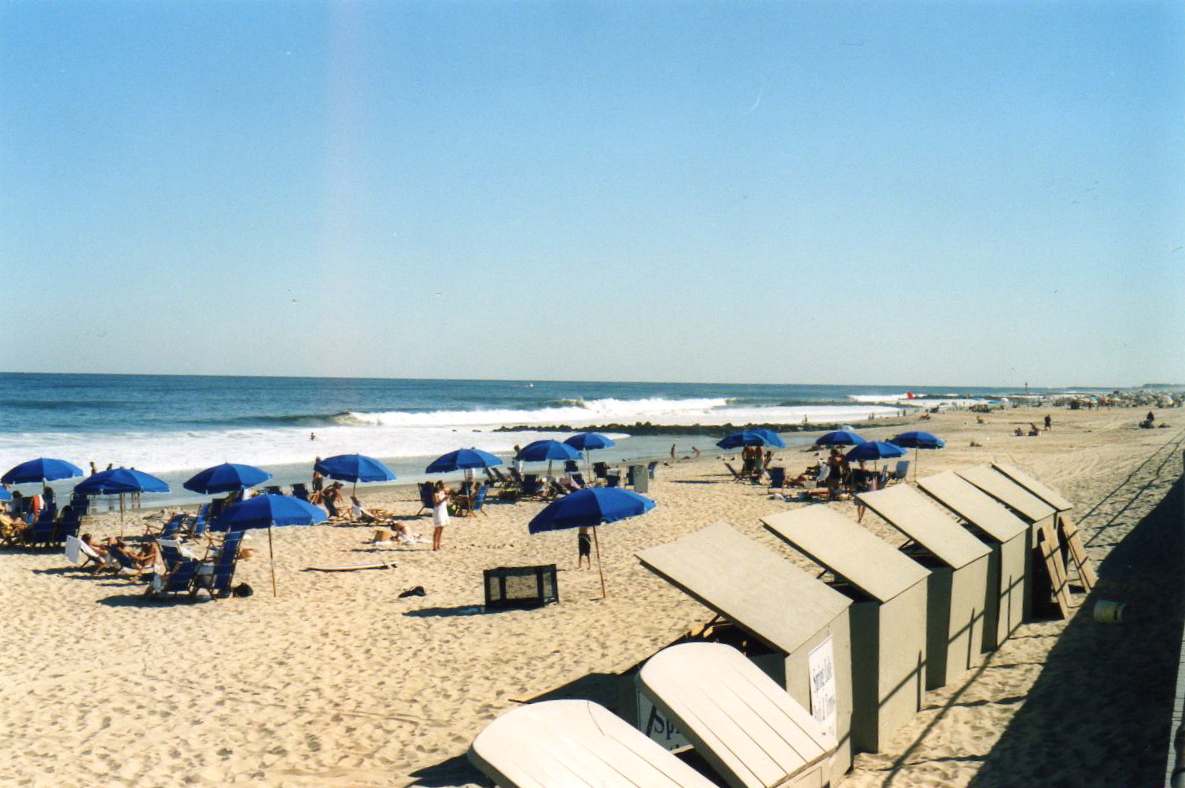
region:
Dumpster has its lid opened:
[631, 518, 862, 785]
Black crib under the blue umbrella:
[482, 560, 559, 609]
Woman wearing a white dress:
[424, 474, 456, 553]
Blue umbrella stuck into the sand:
[528, 471, 665, 616]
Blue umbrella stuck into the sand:
[211, 488, 329, 611]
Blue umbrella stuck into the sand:
[74, 459, 172, 548]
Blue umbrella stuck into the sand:
[0, 454, 86, 506]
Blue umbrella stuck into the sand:
[309, 449, 393, 520]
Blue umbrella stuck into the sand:
[419, 445, 507, 516]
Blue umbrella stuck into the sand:
[887, 420, 942, 475]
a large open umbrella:
[219, 477, 318, 605]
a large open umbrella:
[71, 458, 159, 564]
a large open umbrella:
[4, 437, 61, 519]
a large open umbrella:
[327, 452, 381, 512]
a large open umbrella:
[434, 442, 496, 511]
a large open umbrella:
[517, 433, 579, 504]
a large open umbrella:
[845, 435, 907, 490]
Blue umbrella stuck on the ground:
[524, 482, 661, 598]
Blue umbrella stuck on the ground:
[201, 482, 331, 608]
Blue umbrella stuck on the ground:
[418, 442, 509, 523]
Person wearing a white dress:
[421, 479, 458, 550]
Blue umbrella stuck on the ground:
[511, 423, 582, 505]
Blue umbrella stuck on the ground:
[567, 425, 627, 489]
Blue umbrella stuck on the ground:
[0, 456, 84, 528]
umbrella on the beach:
[543, 491, 668, 536]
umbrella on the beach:
[0, 464, 81, 509]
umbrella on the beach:
[108, 464, 172, 508]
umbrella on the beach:
[189, 464, 243, 492]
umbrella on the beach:
[897, 434, 932, 459]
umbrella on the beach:
[731, 423, 781, 450]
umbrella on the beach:
[814, 423, 866, 448]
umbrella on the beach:
[507, 439, 569, 477]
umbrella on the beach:
[272, 496, 338, 543]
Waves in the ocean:
[4, 356, 1064, 459]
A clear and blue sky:
[0, 0, 1178, 392]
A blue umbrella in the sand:
[516, 470, 675, 610]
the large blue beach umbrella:
[203, 489, 326, 595]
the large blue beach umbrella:
[526, 479, 651, 602]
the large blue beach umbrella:
[5, 455, 82, 541]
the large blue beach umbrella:
[77, 469, 166, 536]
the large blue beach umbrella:
[187, 457, 261, 519]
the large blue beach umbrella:
[314, 450, 391, 529]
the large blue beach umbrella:
[426, 443, 498, 515]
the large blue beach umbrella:
[514, 437, 578, 501]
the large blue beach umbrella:
[897, 428, 942, 478]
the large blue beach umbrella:
[314, 452, 386, 523]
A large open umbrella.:
[532, 479, 642, 617]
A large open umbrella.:
[723, 423, 767, 489]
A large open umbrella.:
[562, 421, 609, 493]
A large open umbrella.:
[427, 446, 496, 513]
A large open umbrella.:
[319, 455, 396, 521]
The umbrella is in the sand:
[506, 467, 678, 637]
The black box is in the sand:
[474, 516, 555, 602]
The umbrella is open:
[204, 491, 334, 606]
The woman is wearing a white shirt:
[413, 459, 462, 563]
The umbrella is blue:
[519, 471, 669, 635]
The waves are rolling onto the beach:
[18, 362, 832, 531]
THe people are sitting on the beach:
[1002, 381, 1084, 487]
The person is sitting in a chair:
[60, 527, 137, 584]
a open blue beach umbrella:
[526, 477, 646, 529]